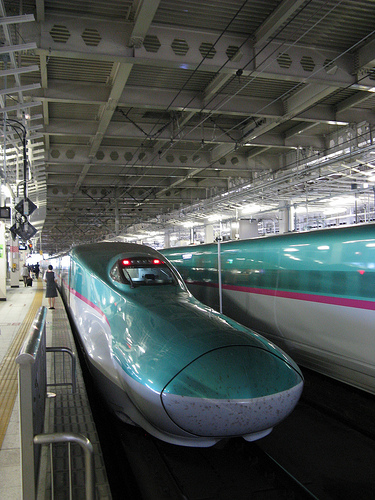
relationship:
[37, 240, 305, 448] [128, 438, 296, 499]
train on railway track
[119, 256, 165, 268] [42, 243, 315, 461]
headlights on train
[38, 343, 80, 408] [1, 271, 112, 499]
metal bar on sidewalk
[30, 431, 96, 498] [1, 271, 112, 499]
metal bar on sidewalk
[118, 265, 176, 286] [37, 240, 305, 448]
screen on train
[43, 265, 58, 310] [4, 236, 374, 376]
woman at station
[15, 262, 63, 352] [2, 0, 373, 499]
sidewalk at train station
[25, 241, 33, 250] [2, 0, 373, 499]
traffic signal at train station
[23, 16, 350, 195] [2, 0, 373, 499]
roofing at train station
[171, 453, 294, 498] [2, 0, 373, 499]
railway track at train station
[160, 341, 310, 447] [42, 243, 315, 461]
train front of train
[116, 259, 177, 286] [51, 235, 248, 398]
windshield of train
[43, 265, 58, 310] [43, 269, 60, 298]
woman in dress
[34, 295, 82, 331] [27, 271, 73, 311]
shoes of woman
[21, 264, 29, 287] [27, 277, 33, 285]
woman rolls luggage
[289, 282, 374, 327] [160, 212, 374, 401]
stripe on train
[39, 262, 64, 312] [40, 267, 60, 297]
woman wears dress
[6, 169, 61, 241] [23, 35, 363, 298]
signs in station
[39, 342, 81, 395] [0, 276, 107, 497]
railing on platform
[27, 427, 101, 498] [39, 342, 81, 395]
railing on railing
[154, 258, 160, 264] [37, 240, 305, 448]
light front train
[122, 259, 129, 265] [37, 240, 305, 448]
headlights front train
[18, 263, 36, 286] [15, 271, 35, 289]
woman rolling luggage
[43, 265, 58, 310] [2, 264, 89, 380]
woman on platform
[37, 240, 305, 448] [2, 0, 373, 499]
train in train station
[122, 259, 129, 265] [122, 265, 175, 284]
headlights on windshield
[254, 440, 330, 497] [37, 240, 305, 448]
tracks for train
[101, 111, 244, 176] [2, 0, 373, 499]
cables at train station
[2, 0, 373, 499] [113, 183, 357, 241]
train station has lights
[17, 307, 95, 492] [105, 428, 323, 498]
safety railing near train track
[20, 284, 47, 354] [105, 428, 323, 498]
safety line near train track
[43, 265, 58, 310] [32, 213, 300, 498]
woman next train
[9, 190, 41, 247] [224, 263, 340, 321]
signs in station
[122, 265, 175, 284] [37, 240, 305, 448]
windshield front train